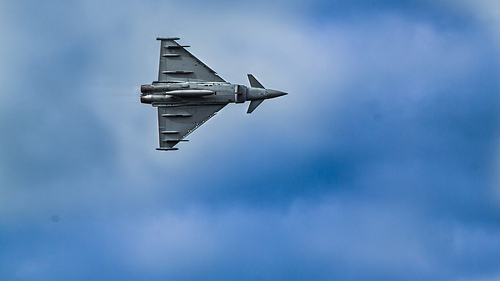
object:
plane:
[139, 37, 291, 151]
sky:
[1, 1, 499, 279]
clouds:
[0, 0, 500, 281]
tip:
[265, 88, 288, 99]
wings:
[157, 106, 226, 151]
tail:
[139, 82, 153, 105]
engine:
[165, 89, 217, 95]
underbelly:
[157, 78, 231, 107]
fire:
[88, 90, 141, 102]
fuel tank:
[140, 83, 191, 93]